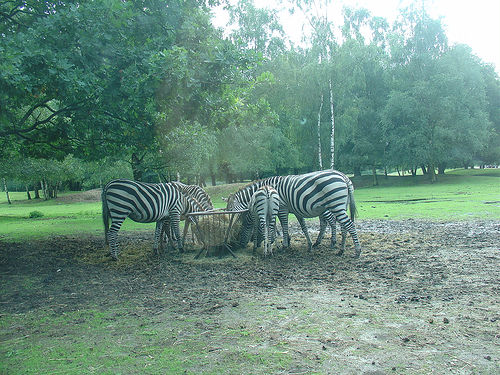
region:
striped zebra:
[87, 163, 213, 259]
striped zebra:
[238, 192, 298, 258]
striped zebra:
[271, 156, 350, 233]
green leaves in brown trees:
[9, 16, 58, 49]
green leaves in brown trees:
[27, 78, 84, 133]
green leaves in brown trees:
[131, 71, 208, 118]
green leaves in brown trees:
[262, 60, 341, 101]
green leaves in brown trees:
[377, 54, 464, 125]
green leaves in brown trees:
[406, 132, 464, 165]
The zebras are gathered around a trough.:
[95, 145, 380, 268]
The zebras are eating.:
[171, 173, 256, 258]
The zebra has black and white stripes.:
[111, 188, 173, 208]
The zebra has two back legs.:
[255, 198, 280, 259]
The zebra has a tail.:
[340, 175, 362, 225]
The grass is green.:
[376, 182, 459, 217]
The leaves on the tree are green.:
[0, 0, 256, 165]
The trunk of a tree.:
[325, 80, 336, 167]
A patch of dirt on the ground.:
[361, 330, 416, 370]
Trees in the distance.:
[214, 31, 492, 172]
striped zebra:
[214, 157, 369, 247]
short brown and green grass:
[17, 257, 70, 309]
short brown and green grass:
[401, 198, 453, 215]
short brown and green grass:
[385, 260, 456, 304]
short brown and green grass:
[60, 303, 166, 358]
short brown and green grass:
[187, 301, 355, 364]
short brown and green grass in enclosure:
[23, 192, 89, 241]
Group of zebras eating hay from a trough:
[95, 167, 375, 265]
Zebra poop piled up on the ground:
[66, 262, 452, 311]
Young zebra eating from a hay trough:
[248, 183, 284, 260]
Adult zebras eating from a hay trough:
[97, 178, 212, 253]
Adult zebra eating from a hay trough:
[225, 166, 364, 256]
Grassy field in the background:
[373, 183, 485, 223]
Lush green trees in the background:
[155, 34, 483, 179]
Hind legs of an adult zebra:
[319, 166, 367, 259]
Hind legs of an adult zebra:
[96, 176, 138, 267]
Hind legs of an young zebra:
[250, 183, 284, 265]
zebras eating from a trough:
[68, 165, 361, 265]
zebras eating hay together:
[87, 171, 379, 264]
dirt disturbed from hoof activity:
[362, 223, 481, 287]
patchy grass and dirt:
[34, 293, 286, 373]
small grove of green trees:
[144, 43, 480, 183]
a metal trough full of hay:
[185, 208, 246, 255]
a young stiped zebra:
[250, 190, 278, 258]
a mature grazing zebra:
[97, 176, 210, 258]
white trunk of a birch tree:
[326, 80, 339, 171]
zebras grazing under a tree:
[8, 48, 453, 339]